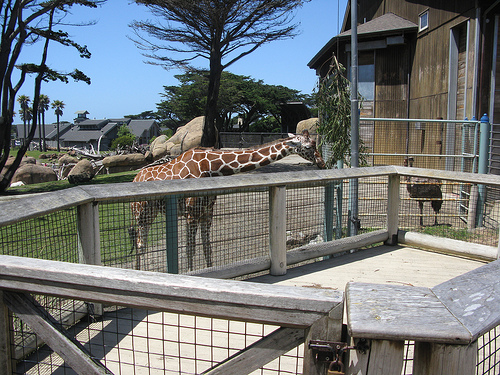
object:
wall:
[373, 55, 440, 119]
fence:
[280, 178, 424, 258]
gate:
[364, 74, 438, 217]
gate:
[293, 123, 425, 205]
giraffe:
[125, 133, 328, 281]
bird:
[392, 147, 456, 236]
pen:
[11, 194, 471, 373]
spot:
[252, 148, 266, 162]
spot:
[169, 159, 184, 177]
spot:
[240, 157, 260, 176]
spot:
[201, 157, 211, 171]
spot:
[223, 150, 236, 162]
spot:
[154, 171, 175, 185]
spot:
[260, 145, 279, 161]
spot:
[198, 157, 217, 177]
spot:
[170, 156, 184, 172]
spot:
[149, 173, 157, 182]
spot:
[185, 158, 202, 178]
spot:
[219, 165, 232, 176]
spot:
[273, 145, 283, 155]